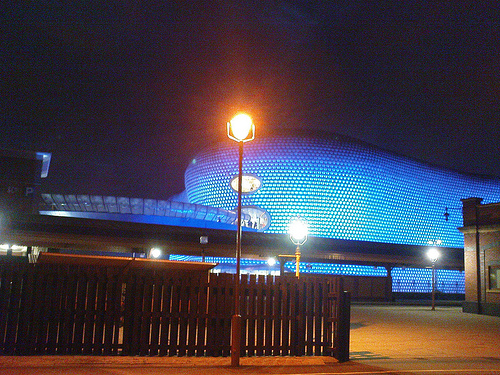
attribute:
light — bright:
[223, 171, 265, 194]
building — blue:
[166, 131, 498, 300]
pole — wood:
[111, 267, 119, 354]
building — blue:
[8, 127, 498, 303]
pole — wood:
[188, 270, 214, 350]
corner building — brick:
[454, 195, 476, 300]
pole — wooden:
[272, 275, 282, 354]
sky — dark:
[1, 4, 498, 198]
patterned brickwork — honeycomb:
[181, 135, 498, 298]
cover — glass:
[35, 185, 240, 232]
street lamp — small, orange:
[209, 110, 256, 350]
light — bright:
[351, 195, 374, 204]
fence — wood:
[14, 238, 348, 366]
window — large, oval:
[227, 173, 263, 195]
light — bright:
[190, 153, 200, 167]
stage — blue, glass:
[32, 184, 257, 231]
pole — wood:
[305, 276, 315, 357]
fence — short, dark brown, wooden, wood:
[3, 260, 351, 360]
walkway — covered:
[1, 240, 497, 305]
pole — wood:
[214, 274, 232, 353]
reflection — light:
[339, 318, 491, 373]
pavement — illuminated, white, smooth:
[360, 300, 422, 337]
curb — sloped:
[4, 350, 344, 373]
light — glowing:
[213, 112, 272, 158]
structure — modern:
[60, 169, 447, 297]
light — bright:
[327, 203, 330, 208]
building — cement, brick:
[4, 143, 47, 217]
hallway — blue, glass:
[23, 187, 263, 232]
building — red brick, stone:
[456, 195, 499, 318]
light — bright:
[290, 175, 350, 202]